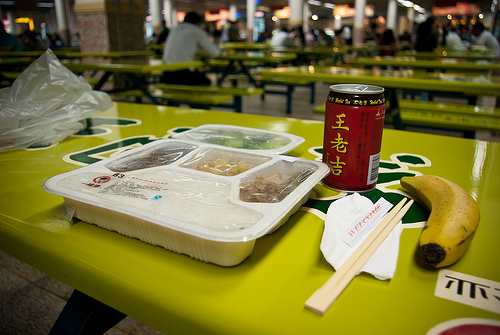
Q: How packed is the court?
A: Not packed.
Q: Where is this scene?
A: Asia.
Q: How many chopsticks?
A: Two.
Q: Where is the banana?
A: On table.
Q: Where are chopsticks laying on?
A: Napkin.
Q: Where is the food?
A: In tray.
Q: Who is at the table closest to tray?
A: A man.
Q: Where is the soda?
A: On table.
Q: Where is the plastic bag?
A: On table.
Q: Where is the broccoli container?
A: Front of tray.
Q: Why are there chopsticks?
A: To eat.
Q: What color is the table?
A: Green.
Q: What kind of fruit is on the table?
A: Banana.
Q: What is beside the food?
A: Plastic bag.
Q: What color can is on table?
A: Red.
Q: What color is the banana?
A: Yellow.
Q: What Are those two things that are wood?
A: Chopsticks.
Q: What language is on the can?
A: Chinese.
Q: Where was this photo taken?
A: A restaurant.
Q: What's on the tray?
A: Food.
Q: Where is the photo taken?
A: Lunch room.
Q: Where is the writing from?
A: Asia.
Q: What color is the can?
A: Red.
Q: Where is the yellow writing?
A: Red can.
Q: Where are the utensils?
A: On napkin.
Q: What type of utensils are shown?
A: Chopsticks.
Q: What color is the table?
A: Green.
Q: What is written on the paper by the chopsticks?
A: Welcome.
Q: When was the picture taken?
A: Daytime.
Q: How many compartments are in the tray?
A: 4.